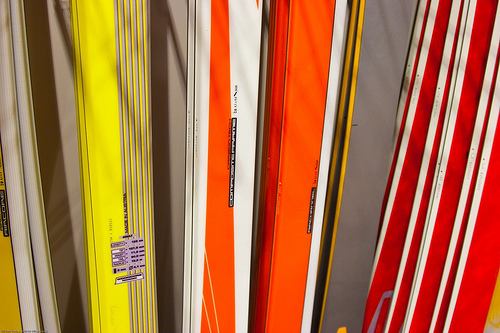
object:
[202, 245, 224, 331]
string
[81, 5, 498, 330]
vertical blinds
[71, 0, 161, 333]
blinds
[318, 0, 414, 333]
blinds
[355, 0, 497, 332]
red blints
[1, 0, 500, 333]
display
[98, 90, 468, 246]
greens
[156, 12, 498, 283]
vertical blind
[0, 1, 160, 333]
blinds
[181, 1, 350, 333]
blinds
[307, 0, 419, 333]
blinds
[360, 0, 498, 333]
blinds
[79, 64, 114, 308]
board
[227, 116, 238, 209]
white sign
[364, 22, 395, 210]
board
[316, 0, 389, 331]
stripe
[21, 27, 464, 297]
wall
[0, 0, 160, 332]
sign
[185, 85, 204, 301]
stripe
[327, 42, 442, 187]
board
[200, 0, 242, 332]
stripe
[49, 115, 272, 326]
blind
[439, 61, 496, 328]
line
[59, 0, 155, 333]
yellow board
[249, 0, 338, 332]
blind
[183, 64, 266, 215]
board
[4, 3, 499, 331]
wall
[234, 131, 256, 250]
white stripe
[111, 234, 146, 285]
label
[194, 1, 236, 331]
orange stripe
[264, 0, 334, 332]
orange stripe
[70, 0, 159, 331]
stripe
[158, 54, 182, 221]
gray stripe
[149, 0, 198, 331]
stripe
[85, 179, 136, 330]
wall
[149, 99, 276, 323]
wall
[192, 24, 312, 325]
wall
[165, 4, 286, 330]
wall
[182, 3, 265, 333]
stripe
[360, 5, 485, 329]
wall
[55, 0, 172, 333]
blinds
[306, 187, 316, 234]
label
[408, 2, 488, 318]
connector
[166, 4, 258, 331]
board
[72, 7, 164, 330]
board